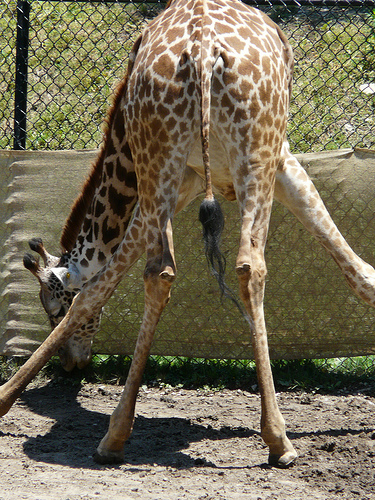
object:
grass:
[79, 365, 94, 374]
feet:
[267, 447, 298, 471]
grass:
[156, 356, 181, 379]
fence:
[3, 2, 362, 381]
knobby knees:
[235, 253, 266, 301]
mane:
[50, 55, 135, 259]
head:
[23, 235, 98, 374]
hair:
[197, 201, 254, 326]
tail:
[193, 66, 254, 321]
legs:
[284, 161, 375, 313]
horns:
[22, 251, 44, 282]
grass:
[2, 358, 12, 384]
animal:
[3, 0, 375, 460]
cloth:
[2, 143, 374, 364]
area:
[0, 7, 373, 383]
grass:
[337, 354, 372, 390]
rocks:
[355, 79, 374, 94]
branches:
[360, 10, 375, 33]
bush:
[362, 69, 375, 78]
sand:
[103, 460, 119, 481]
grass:
[177, 362, 197, 384]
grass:
[89, 352, 116, 371]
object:
[327, 357, 347, 369]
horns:
[27, 236, 54, 265]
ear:
[49, 265, 79, 289]